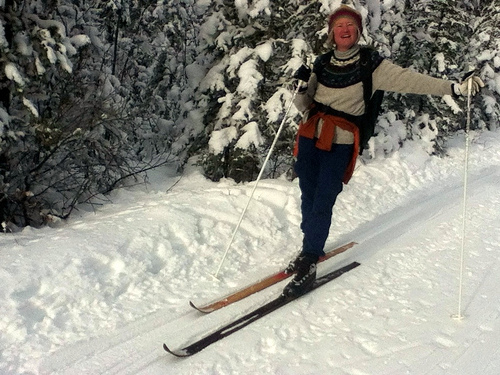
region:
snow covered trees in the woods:
[80, 56, 234, 171]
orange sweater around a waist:
[294, 111, 359, 150]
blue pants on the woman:
[287, 145, 347, 255]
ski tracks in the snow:
[377, 212, 402, 244]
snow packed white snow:
[71, 248, 136, 302]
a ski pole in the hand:
[459, 64, 479, 264]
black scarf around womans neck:
[300, 51, 384, 95]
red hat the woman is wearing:
[322, 4, 368, 17]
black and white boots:
[278, 263, 322, 303]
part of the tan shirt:
[322, 96, 361, 111]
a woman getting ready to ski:
[162, 6, 477, 357]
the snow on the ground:
[3, 147, 496, 370]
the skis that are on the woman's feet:
[170, 235, 356, 355]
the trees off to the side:
[0, 0, 486, 165]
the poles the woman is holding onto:
[202, 78, 474, 322]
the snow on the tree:
[203, 49, 298, 160]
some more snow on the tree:
[417, 7, 499, 113]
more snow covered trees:
[33, 6, 233, 173]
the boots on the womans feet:
[276, 255, 321, 301]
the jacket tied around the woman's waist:
[299, 110, 361, 160]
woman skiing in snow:
[161, 4, 483, 356]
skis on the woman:
[143, 238, 361, 358]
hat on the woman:
[328, 4, 367, 27]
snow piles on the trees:
[196, 15, 266, 152]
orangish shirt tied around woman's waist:
[293, 109, 361, 183]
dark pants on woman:
[293, 138, 355, 261]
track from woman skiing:
[378, 212, 425, 229]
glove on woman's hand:
[452, 65, 486, 100]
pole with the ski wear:
[454, 72, 480, 322]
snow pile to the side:
[6, 239, 157, 324]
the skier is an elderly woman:
[283, 12, 476, 286]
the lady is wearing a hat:
[330, 4, 360, 28]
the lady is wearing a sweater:
[297, 50, 451, 156]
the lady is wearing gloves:
[461, 75, 483, 100]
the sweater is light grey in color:
[300, 45, 456, 147]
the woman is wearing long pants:
[297, 145, 354, 266]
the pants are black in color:
[293, 145, 357, 271]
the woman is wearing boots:
[282, 243, 329, 293]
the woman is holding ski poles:
[454, 68, 475, 323]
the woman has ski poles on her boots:
[157, 238, 363, 359]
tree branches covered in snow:
[4, 2, 496, 222]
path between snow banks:
[28, 140, 494, 373]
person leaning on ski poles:
[163, 4, 480, 358]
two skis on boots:
[161, 238, 358, 364]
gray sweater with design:
[296, 44, 454, 143]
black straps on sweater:
[310, 45, 383, 110]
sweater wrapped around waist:
[285, 105, 372, 253]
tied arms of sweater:
[292, 110, 359, 185]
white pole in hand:
[207, 55, 315, 279]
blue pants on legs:
[291, 130, 353, 262]